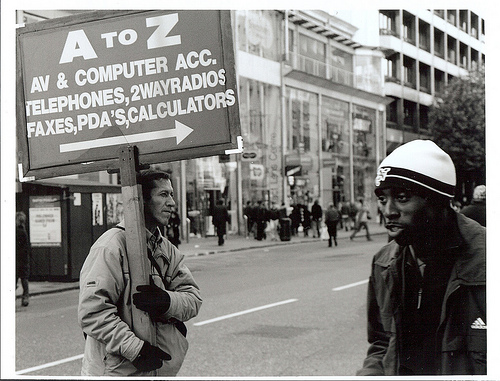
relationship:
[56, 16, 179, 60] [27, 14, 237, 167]
alphabet on sign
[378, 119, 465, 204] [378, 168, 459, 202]
hat has stripes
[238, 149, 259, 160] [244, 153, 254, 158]
logo of mastercard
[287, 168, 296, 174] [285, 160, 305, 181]
subway on sign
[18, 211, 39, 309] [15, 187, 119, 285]
woman by busstop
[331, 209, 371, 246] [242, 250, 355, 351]
people in street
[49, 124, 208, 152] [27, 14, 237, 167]
arrow on sign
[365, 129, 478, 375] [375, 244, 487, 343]
man has jacket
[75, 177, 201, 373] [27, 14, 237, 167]
man has sign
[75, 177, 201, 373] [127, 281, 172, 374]
man has gloves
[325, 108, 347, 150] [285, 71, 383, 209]
glass on building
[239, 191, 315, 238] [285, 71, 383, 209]
people by building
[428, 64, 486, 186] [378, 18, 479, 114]
tree by building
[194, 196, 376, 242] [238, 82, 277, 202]
crowd by store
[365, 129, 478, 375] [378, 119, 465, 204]
man wearing beanie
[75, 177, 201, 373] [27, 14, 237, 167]
man holding sign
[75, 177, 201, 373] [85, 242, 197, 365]
man wearing jacket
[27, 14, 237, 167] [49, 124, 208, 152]
sign with arrow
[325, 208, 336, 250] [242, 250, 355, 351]
man in street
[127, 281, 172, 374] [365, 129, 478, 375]
gloves on man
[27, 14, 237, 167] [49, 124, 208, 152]
sign has arrow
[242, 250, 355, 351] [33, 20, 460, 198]
street in city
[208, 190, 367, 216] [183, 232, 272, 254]
pedestrians on sidewalk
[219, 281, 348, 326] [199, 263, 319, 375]
lines on road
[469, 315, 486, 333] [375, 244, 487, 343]
logo on jacket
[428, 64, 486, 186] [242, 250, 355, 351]
tree by street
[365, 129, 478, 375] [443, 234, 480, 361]
man in coat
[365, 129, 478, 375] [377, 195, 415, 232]
man has face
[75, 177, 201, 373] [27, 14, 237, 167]
man carrying sign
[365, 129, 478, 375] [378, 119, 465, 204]
man with hat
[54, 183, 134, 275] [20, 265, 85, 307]
building on curb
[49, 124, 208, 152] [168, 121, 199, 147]
arrow pointing right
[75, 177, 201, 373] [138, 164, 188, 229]
man has head